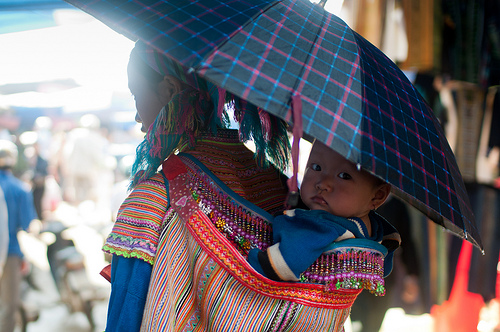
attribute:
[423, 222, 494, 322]
object — blurry, red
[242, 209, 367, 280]
top — blue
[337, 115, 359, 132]
stripe — red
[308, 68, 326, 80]
stripe — red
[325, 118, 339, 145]
stripe — red and blue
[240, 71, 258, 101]
stripe — red and blue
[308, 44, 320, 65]
stripe — red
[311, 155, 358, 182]
eyes — dark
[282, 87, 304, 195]
ribbon — purple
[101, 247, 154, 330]
shirt sleeve — long, blue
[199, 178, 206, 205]
rows — colorful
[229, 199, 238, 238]
rows — colorful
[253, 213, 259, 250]
rows — colorful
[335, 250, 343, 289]
rows — colorful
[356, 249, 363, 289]
rows — colorful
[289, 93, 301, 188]
ribbon — red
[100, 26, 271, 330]
woman — blue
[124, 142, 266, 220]
shirt — colorful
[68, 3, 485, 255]
umbrella`s top — open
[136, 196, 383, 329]
stripes — mulit-colored, thin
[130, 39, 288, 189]
scarf — tied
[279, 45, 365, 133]
checkers — blue, purple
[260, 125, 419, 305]
baby — small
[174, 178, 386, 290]
beading — fuchsia, flower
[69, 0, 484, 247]
umbrella — black, black plastic, blue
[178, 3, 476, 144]
umbrella — open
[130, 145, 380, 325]
carrier — colorful, beaded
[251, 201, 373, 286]
outfit — blue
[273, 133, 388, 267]
outfit — blue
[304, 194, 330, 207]
lips — small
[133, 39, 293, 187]
yarn — blue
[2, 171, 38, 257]
shirt — blue